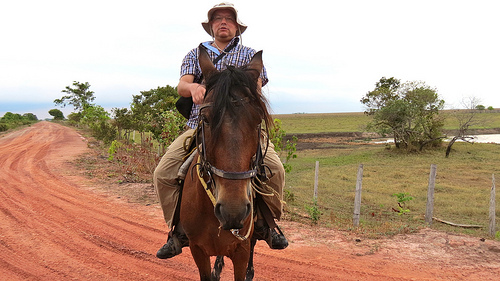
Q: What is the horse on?
A: Dirt road.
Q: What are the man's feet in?
A: Stirrups.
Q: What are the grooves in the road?
A: Ruts.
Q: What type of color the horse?
A: Brown.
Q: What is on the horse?
A: A male.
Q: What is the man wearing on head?
A: Hat.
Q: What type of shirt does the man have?
A: Plaid.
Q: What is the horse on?
A: Clay road.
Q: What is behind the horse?
A: Fence.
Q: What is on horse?
A: Reins.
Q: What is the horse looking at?
A: Camera.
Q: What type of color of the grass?
A: Green.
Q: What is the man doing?
A: Riding.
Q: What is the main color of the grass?
A: Green.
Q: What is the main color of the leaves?
A: Green.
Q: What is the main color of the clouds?
A: White.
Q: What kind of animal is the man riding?
A: A horse.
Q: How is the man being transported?
A: By horse.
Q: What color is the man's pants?
A: Tan.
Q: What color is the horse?
A: Brown.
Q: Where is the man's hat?
A: On his head.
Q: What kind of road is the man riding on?
A: Dirt.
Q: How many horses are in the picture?
A: One.